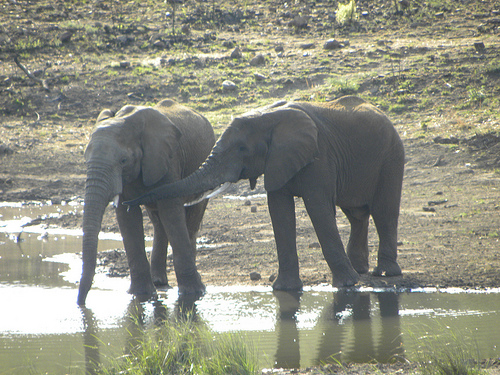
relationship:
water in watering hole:
[0, 200, 499, 373] [2, 42, 496, 372]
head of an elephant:
[209, 109, 331, 206] [142, 98, 406, 289]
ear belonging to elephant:
[264, 106, 317, 192] [119, 92, 408, 294]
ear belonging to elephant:
[139, 106, 181, 182] [76, 96, 222, 306]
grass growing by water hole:
[95, 310, 245, 374] [4, 336, 267, 374]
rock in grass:
[247, 269, 263, 287] [98, 320, 493, 373]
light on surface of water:
[205, 271, 250, 317] [289, 265, 453, 347]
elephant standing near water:
[119, 92, 408, 294] [0, 200, 499, 373]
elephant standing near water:
[76, 96, 222, 306] [0, 200, 499, 373]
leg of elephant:
[303, 199, 366, 296] [188, 95, 432, 317]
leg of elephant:
[114, 207, 156, 301] [37, 108, 224, 333]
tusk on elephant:
[181, 180, 233, 208] [119, 92, 408, 294]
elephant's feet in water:
[121, 270, 209, 299] [3, 283, 498, 372]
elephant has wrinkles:
[64, 99, 230, 309] [78, 158, 115, 211]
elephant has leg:
[119, 97, 404, 292] [263, 197, 308, 291]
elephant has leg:
[119, 97, 404, 292] [305, 200, 359, 288]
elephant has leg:
[119, 97, 404, 292] [339, 213, 372, 272]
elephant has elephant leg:
[119, 97, 404, 292] [370, 167, 403, 259]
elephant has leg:
[76, 96, 222, 306] [115, 224, 157, 299]